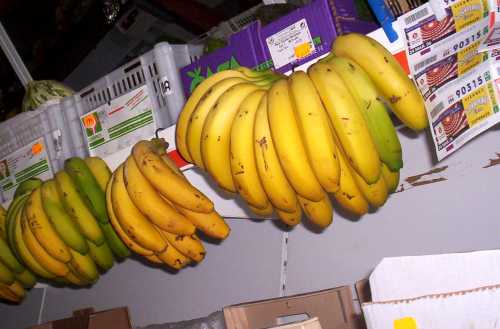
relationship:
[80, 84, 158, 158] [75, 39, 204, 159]
label on top of bin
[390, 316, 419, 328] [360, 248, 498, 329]
sticker on box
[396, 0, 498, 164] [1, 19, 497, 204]
coupon in front of shelf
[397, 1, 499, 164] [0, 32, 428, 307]
paper beside bananas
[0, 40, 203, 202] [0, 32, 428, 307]
containers above bananas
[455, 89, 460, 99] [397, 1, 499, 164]
number printed on paper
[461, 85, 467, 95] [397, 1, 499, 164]
number 0 printed on paper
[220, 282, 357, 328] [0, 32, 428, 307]
box under bananas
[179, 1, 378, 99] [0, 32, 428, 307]
box above bananas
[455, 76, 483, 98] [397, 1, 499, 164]
numbers printed on paper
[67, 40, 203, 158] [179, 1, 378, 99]
crate beside box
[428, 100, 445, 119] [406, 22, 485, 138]
bar code on paper